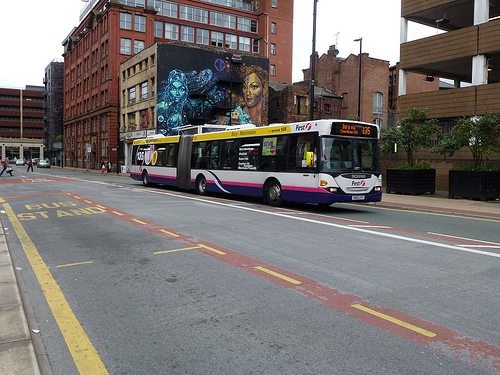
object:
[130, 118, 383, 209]
bus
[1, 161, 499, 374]
highway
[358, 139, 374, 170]
door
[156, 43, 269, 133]
posters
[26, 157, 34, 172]
person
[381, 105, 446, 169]
plant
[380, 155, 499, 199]
wall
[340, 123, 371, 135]
words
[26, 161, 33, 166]
blouse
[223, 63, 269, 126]
woman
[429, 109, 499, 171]
tree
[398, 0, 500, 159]
parking ramp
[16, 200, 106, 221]
words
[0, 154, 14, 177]
person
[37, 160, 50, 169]
car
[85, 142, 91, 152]
sign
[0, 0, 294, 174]
building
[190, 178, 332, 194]
stripe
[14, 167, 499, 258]
line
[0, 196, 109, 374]
line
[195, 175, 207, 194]
wheel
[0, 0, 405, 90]
sky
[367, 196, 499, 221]
sidewalk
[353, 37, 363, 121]
street light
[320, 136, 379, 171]
windshield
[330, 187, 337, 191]
light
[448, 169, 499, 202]
planter